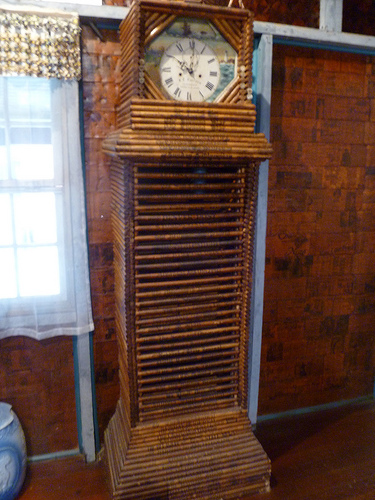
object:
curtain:
[0, 1, 95, 340]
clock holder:
[102, 1, 274, 500]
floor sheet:
[282, 443, 370, 496]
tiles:
[293, 91, 352, 166]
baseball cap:
[0, 8, 82, 81]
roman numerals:
[175, 42, 182, 51]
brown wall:
[0, 1, 375, 462]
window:
[0, 113, 59, 256]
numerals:
[162, 40, 217, 100]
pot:
[0, 401, 26, 499]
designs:
[0, 446, 22, 497]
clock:
[160, 38, 220, 102]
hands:
[173, 48, 194, 73]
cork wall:
[292, 85, 365, 303]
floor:
[16, 400, 374, 499]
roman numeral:
[187, 91, 192, 100]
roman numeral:
[210, 71, 218, 76]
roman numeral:
[189, 40, 195, 49]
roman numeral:
[163, 67, 170, 72]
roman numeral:
[174, 87, 182, 97]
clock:
[144, 15, 237, 102]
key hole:
[179, 72, 182, 75]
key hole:
[199, 74, 202, 78]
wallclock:
[114, 0, 256, 131]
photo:
[0, 0, 375, 499]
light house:
[225, 49, 228, 62]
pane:
[0, 72, 62, 298]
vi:
[187, 91, 192, 101]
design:
[143, 45, 164, 68]